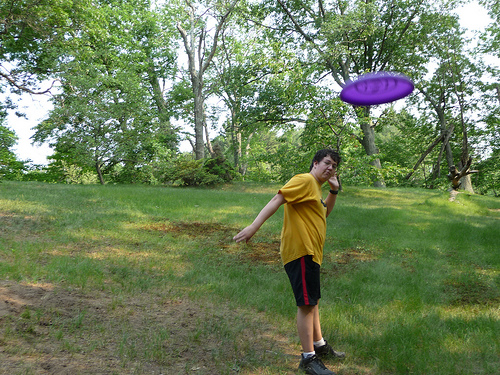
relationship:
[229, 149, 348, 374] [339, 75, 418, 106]
boy throwing frisbee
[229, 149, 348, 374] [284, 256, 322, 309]
boy wearing shorts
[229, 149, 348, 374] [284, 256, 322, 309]
boy in shorts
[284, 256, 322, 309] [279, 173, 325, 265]
shorts are below shirt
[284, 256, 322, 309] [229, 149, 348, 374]
shorts are on boy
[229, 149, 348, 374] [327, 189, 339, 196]
boy wearing a watch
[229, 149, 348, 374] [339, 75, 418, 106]
boy playing with a frisbee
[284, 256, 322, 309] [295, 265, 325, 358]
shorts are on legs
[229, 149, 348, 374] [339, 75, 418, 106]
boy tossing frisbee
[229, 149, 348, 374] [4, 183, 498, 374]
boy playing in grass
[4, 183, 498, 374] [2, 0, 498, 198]
grass near trees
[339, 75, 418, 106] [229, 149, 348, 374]
frisbee in front of boy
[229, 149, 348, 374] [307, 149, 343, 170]
boy has hair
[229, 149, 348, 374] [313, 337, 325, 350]
boy wearing a sock